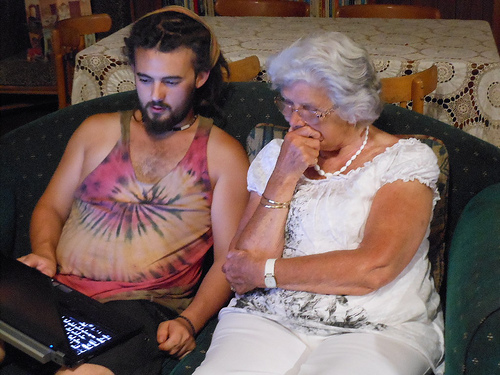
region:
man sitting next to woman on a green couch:
[6, 10, 494, 284]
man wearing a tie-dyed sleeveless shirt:
[25, 15, 238, 285]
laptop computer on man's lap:
[0, 42, 210, 368]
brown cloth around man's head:
[119, 2, 224, 136]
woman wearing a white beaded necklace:
[267, 30, 382, 180]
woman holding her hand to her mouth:
[252, 33, 367, 215]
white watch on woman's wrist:
[225, 251, 297, 293]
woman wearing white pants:
[199, 313, 437, 374]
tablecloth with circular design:
[78, 10, 498, 122]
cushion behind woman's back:
[245, 35, 450, 315]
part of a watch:
[252, 247, 294, 294]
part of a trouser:
[238, 346, 258, 373]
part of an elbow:
[358, 272, 383, 297]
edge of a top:
[356, 300, 400, 342]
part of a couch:
[459, 277, 493, 323]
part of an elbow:
[355, 264, 402, 291]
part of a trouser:
[348, 343, 372, 369]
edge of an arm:
[311, 271, 371, 304]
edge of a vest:
[141, 154, 174, 202]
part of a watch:
[257, 251, 282, 283]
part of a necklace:
[339, 145, 364, 154]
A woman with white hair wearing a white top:
[215, 12, 457, 362]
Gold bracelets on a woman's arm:
[254, 185, 293, 220]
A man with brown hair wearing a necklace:
[50, 5, 251, 150]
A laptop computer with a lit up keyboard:
[3, 222, 148, 370]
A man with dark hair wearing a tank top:
[12, 10, 249, 364]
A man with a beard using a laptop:
[3, 12, 260, 369]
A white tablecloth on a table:
[376, 13, 496, 87]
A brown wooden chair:
[37, 8, 109, 103]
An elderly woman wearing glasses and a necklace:
[248, 29, 392, 198]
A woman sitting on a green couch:
[223, 22, 493, 373]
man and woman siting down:
[34, 12, 471, 364]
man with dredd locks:
[89, 24, 239, 130]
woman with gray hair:
[245, 42, 419, 152]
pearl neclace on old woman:
[282, 131, 397, 182]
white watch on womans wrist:
[232, 225, 323, 327]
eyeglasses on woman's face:
[259, 87, 353, 142]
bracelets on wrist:
[252, 179, 314, 234]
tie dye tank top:
[70, 115, 215, 313]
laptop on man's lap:
[10, 226, 120, 373]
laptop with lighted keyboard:
[2, 260, 108, 373]